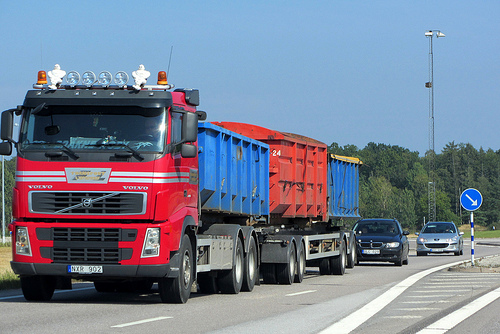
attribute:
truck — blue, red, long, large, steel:
[2, 62, 367, 303]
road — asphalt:
[2, 239, 498, 332]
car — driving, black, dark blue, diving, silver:
[352, 216, 411, 264]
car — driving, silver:
[414, 219, 462, 256]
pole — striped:
[456, 187, 483, 265]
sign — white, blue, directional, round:
[458, 188, 485, 211]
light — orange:
[157, 71, 168, 86]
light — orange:
[36, 69, 49, 86]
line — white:
[309, 253, 490, 333]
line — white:
[408, 284, 500, 333]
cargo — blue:
[195, 123, 272, 222]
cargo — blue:
[327, 154, 365, 219]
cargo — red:
[211, 121, 330, 221]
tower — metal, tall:
[424, 30, 446, 222]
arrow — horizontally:
[465, 192, 478, 208]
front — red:
[14, 91, 167, 267]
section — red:
[9, 89, 200, 278]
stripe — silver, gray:
[14, 169, 194, 179]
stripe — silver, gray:
[15, 175, 202, 185]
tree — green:
[359, 176, 417, 231]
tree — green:
[384, 160, 458, 224]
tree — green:
[434, 145, 499, 230]